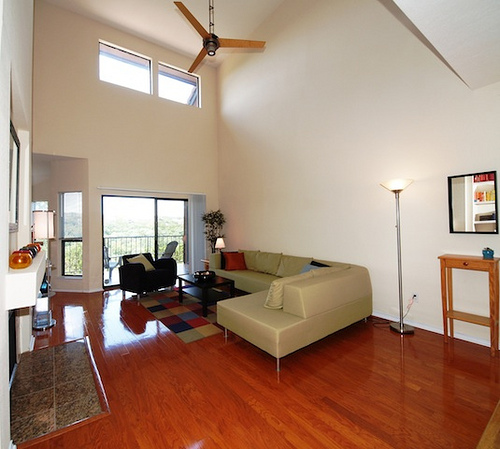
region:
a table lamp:
[211, 232, 228, 254]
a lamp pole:
[390, 189, 405, 327]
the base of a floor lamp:
[387, 317, 417, 337]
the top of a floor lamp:
[377, 176, 418, 195]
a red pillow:
[210, 242, 255, 278]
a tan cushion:
[248, 245, 283, 274]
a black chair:
[108, 240, 183, 306]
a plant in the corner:
[198, 205, 230, 256]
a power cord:
[367, 288, 422, 331]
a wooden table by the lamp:
[432, 244, 498, 357]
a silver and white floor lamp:
[372, 177, 416, 337]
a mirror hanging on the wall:
[445, 169, 498, 234]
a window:
[59, 187, 85, 280]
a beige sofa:
[207, 245, 374, 372]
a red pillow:
[220, 250, 247, 271]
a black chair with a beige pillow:
[117, 250, 177, 302]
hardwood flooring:
[113, 380, 478, 447]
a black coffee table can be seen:
[175, 269, 234, 314]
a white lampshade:
[213, 235, 225, 250]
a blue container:
[480, 246, 495, 260]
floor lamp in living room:
[28, 200, 68, 329]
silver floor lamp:
[361, 159, 428, 353]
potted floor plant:
[196, 197, 241, 302]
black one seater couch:
[109, 238, 187, 313]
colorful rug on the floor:
[121, 272, 280, 367]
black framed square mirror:
[435, 159, 498, 258]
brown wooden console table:
[437, 245, 499, 357]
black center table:
[162, 246, 279, 332]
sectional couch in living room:
[182, 227, 387, 378]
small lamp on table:
[206, 229, 250, 274]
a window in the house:
[96, 40, 156, 97]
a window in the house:
[154, 59, 204, 106]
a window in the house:
[100, 193, 161, 287]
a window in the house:
[153, 190, 193, 270]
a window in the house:
[62, 237, 82, 270]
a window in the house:
[56, 185, 84, 241]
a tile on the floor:
[54, 340, 81, 362]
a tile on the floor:
[52, 363, 89, 383]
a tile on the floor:
[48, 380, 89, 405]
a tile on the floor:
[56, 399, 98, 422]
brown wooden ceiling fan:
[156, 2, 301, 106]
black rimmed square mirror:
[430, 152, 499, 260]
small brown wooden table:
[419, 232, 499, 362]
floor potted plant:
[186, 188, 238, 283]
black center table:
[164, 260, 251, 335]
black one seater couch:
[95, 211, 204, 320]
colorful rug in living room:
[130, 267, 258, 359]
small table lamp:
[206, 226, 239, 278]